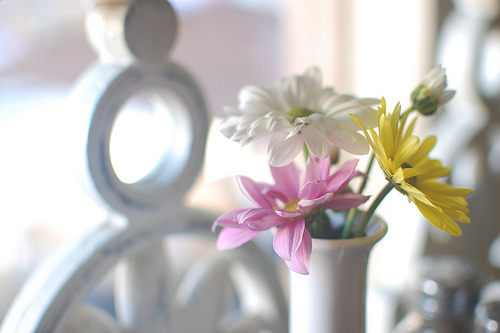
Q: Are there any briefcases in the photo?
A: No, there are no briefcases.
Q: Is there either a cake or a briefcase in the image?
A: No, there are no briefcases or cakes.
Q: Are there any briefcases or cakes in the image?
A: No, there are no briefcases or cakes.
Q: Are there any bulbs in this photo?
A: No, there are no bulbs.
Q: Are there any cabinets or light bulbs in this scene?
A: No, there are no light bulbs or cabinets.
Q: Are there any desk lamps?
A: No, there are no desk lamps.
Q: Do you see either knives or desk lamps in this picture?
A: No, there are no desk lamps or knives.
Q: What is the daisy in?
A: The daisy is in the vase.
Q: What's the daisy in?
A: The daisy is in the vase.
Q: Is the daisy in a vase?
A: Yes, the daisy is in a vase.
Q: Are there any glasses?
A: No, there are no glasses.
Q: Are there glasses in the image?
A: No, there are no glasses.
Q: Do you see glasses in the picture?
A: No, there are no glasses.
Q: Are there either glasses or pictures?
A: No, there are no glasses or pictures.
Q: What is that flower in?
A: The flower is in the vase.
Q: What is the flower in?
A: The flower is in the vase.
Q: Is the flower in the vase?
A: Yes, the flower is in the vase.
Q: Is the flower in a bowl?
A: No, the flower is in the vase.